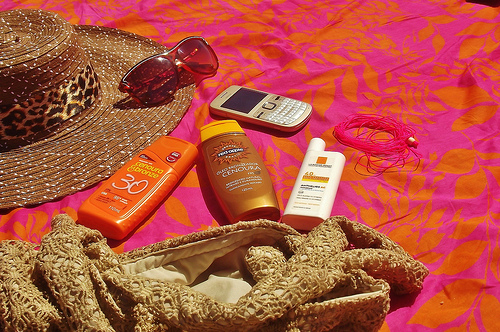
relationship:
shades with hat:
[115, 36, 216, 108] [2, 6, 194, 210]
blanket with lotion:
[2, 1, 497, 330] [283, 137, 343, 229]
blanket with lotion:
[2, 1, 497, 330] [198, 118, 279, 220]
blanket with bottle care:
[2, 1, 497, 330] [78, 135, 199, 241]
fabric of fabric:
[1, 223, 429, 330] [1, 213, 429, 330]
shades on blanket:
[115, 37, 220, 106] [2, 1, 497, 330]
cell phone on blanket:
[194, 79, 297, 138] [376, 9, 480, 118]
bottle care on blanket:
[283, 138, 347, 231] [2, 1, 497, 330]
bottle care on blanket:
[200, 120, 282, 225] [266, 23, 498, 251]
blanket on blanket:
[2, 1, 497, 330] [2, 1, 497, 330]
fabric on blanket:
[1, 213, 429, 330] [2, 1, 497, 330]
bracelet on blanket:
[333, 113, 424, 174] [427, 2, 497, 329]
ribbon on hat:
[0, 57, 101, 151] [7, 9, 203, 223]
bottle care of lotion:
[78, 135, 199, 241] [60, 114, 353, 237]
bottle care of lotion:
[200, 120, 282, 225] [60, 114, 353, 237]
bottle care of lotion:
[283, 138, 347, 231] [60, 114, 353, 237]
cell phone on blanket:
[209, 84, 314, 131] [2, 1, 497, 330]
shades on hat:
[115, 36, 216, 108] [7, 9, 203, 223]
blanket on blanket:
[2, 1, 497, 330] [274, 44, 479, 184]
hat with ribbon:
[0, 9, 195, 210] [0, 65, 100, 151]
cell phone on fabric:
[209, 84, 314, 131] [1, 213, 429, 330]